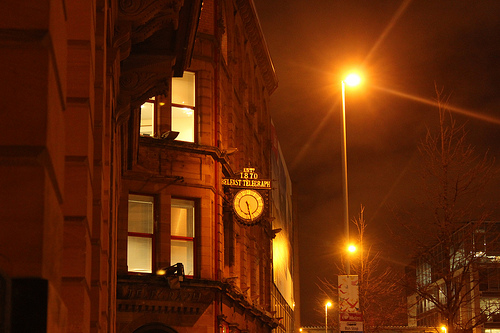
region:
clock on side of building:
[234, 186, 269, 227]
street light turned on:
[329, 58, 374, 108]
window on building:
[165, 195, 195, 282]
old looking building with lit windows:
[5, 0, 281, 326]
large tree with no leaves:
[387, 77, 494, 324]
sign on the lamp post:
[336, 272, 367, 330]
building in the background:
[404, 224, 499, 327]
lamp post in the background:
[321, 300, 332, 329]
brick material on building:
[0, 0, 113, 325]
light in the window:
[174, 65, 194, 144]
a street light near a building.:
[318, 26, 405, 146]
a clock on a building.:
[215, 138, 276, 248]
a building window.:
[117, 178, 211, 289]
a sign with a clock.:
[219, 151, 284, 235]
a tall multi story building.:
[395, 230, 495, 332]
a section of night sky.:
[403, 126, 470, 204]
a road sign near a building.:
[323, 257, 369, 328]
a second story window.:
[170, 68, 203, 139]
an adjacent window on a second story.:
[129, 63, 177, 162]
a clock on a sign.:
[226, 171, 277, 233]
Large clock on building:
[228, 190, 276, 232]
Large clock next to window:
[232, 188, 271, 233]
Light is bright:
[330, 56, 364, 91]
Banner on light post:
[336, 267, 363, 329]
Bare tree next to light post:
[364, 78, 499, 331]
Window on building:
[120, 186, 198, 278]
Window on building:
[140, 62, 208, 148]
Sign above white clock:
[220, 165, 275, 190]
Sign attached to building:
[222, 166, 272, 190]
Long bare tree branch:
[433, 77, 454, 331]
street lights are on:
[309, 44, 416, 327]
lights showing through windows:
[129, 72, 189, 276]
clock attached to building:
[206, 150, 303, 245]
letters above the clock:
[213, 161, 278, 189]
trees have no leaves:
[311, 27, 498, 329]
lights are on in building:
[407, 227, 498, 331]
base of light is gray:
[331, 254, 376, 326]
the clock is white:
[227, 182, 283, 231]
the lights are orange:
[333, 42, 371, 314]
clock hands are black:
[240, 192, 262, 229]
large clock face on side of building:
[227, 186, 267, 223]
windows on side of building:
[107, 190, 203, 277]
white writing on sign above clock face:
[219, 160, 286, 190]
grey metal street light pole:
[333, 90, 359, 237]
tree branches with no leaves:
[409, 122, 483, 242]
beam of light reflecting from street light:
[383, 75, 418, 117]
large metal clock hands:
[242, 199, 252, 219]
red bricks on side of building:
[2, 47, 89, 259]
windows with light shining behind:
[165, 69, 200, 145]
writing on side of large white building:
[335, 307, 367, 330]